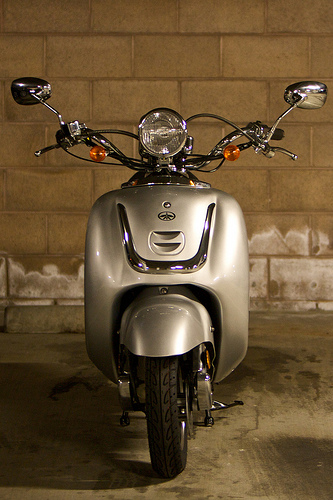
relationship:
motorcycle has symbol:
[6, 75, 330, 478] [152, 210, 181, 226]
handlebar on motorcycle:
[33, 122, 93, 161] [6, 75, 330, 478]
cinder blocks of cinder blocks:
[0, 3, 333, 318] [0, 3, 328, 317]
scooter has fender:
[6, 75, 330, 478] [115, 294, 215, 361]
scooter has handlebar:
[6, 75, 330, 478] [33, 122, 93, 161]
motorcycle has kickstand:
[6, 75, 330, 478] [199, 393, 252, 433]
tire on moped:
[139, 355, 195, 488] [6, 75, 330, 478]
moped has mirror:
[6, 75, 330, 478] [282, 82, 329, 114]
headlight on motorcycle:
[137, 107, 189, 157] [6, 75, 330, 478]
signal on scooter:
[84, 141, 117, 166] [6, 75, 330, 478]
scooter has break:
[6, 75, 330, 478] [204, 113, 305, 176]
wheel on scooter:
[139, 355, 195, 488] [6, 75, 330, 478]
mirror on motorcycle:
[10, 73, 53, 109] [6, 75, 330, 478]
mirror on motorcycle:
[282, 82, 329, 114] [6, 75, 330, 478]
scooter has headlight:
[6, 75, 330, 478] [137, 107, 189, 157]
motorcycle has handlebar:
[6, 75, 330, 478] [33, 122, 93, 161]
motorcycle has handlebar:
[6, 75, 330, 478] [250, 114, 305, 162]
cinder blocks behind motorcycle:
[0, 3, 333, 318] [6, 75, 330, 478]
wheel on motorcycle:
[139, 355, 195, 488] [6, 75, 330, 478]